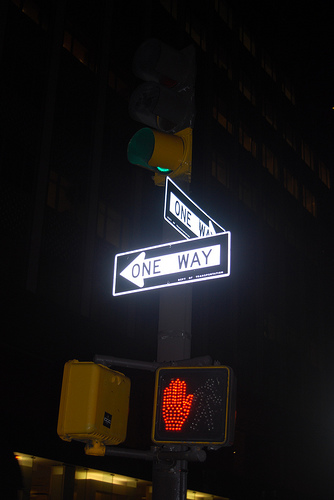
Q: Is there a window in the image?
A: Yes, there is a window.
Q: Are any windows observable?
A: Yes, there is a window.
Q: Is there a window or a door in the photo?
A: Yes, there is a window.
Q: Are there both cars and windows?
A: No, there is a window but no cars.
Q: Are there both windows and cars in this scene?
A: No, there is a window but no cars.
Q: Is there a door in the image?
A: No, there are no doors.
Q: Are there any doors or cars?
A: No, there are no doors or cars.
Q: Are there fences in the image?
A: No, there are no fences.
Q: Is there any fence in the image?
A: No, there are no fences.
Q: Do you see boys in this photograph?
A: No, there are no boys.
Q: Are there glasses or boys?
A: No, there are no boys or glasses.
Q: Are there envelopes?
A: No, there are no envelopes.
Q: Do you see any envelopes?
A: No, there are no envelopes.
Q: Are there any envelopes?
A: No, there are no envelopes.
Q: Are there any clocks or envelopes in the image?
A: No, there are no envelopes or clocks.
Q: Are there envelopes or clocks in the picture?
A: No, there are no envelopes or clocks.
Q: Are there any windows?
A: Yes, there is a window.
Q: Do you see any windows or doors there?
A: Yes, there is a window.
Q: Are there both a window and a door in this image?
A: No, there is a window but no doors.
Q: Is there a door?
A: No, there are no doors.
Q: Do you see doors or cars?
A: No, there are no doors or cars.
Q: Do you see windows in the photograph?
A: Yes, there is a window.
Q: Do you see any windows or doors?
A: Yes, there is a window.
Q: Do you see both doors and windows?
A: No, there is a window but no doors.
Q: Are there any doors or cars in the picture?
A: No, there are no cars or doors.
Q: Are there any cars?
A: No, there are no cars.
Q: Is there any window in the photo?
A: Yes, there is a window.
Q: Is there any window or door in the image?
A: Yes, there is a window.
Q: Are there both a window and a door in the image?
A: No, there is a window but no doors.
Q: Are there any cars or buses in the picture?
A: No, there are no cars or buses.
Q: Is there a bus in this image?
A: No, there are no buses.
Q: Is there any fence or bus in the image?
A: No, there are no buses or fences.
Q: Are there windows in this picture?
A: Yes, there is a window.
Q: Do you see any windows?
A: Yes, there is a window.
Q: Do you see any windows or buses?
A: Yes, there is a window.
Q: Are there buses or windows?
A: Yes, there is a window.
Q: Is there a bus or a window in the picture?
A: Yes, there is a window.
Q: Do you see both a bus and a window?
A: No, there is a window but no buses.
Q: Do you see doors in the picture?
A: No, there are no doors.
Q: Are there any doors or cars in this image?
A: No, there are no doors or cars.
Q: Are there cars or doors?
A: No, there are no doors or cars.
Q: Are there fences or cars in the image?
A: No, there are no cars or fences.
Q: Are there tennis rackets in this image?
A: No, there are no tennis rackets.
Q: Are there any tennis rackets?
A: No, there are no tennis rackets.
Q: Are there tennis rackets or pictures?
A: No, there are no tennis rackets or pictures.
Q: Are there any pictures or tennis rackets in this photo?
A: No, there are no tennis rackets or pictures.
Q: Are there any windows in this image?
A: Yes, there are windows.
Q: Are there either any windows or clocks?
A: Yes, there are windows.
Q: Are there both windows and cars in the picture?
A: No, there are windows but no cars.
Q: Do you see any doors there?
A: No, there are no doors.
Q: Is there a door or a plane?
A: No, there are no doors or airplanes.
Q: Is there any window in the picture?
A: Yes, there is a window.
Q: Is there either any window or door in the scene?
A: Yes, there is a window.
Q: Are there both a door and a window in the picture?
A: No, there is a window but no doors.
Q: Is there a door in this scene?
A: No, there are no doors.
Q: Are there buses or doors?
A: No, there are no doors or buses.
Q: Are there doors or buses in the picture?
A: No, there are no doors or buses.